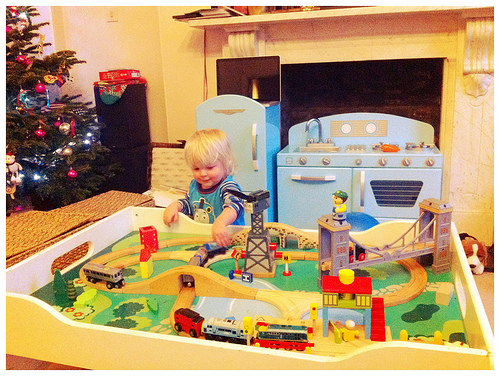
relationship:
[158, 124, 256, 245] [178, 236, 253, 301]
child owns train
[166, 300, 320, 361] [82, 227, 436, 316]
toy on track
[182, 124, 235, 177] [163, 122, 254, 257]
hair of child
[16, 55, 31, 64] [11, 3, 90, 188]
decoration on christmas tree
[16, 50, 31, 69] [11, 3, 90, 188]
decoration on christmas tree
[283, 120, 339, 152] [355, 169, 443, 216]
sink near stove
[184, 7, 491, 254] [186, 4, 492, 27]
fireplace has mantle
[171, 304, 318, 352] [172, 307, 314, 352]
cars on train